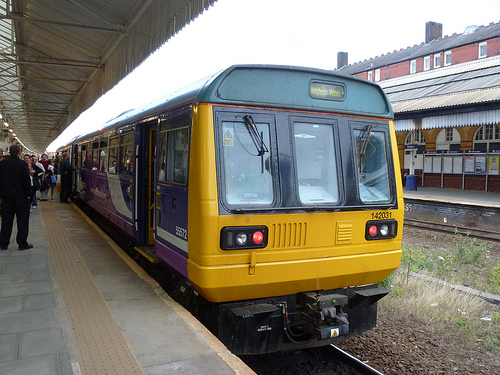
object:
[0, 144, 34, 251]
man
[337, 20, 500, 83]
roof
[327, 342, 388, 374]
metal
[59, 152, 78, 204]
man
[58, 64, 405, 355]
bus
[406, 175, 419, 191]
trash can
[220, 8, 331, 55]
sky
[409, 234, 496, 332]
grass area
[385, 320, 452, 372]
gravel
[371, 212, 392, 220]
142031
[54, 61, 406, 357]
train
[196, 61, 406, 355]
front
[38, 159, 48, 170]
shirt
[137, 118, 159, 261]
door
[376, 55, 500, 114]
roof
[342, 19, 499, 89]
wall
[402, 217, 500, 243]
tracks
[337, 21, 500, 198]
building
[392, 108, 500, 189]
store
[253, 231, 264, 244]
red light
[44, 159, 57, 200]
person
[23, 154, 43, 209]
person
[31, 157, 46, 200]
person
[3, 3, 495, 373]
station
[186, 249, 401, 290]
bumper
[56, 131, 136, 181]
windows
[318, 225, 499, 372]
ground